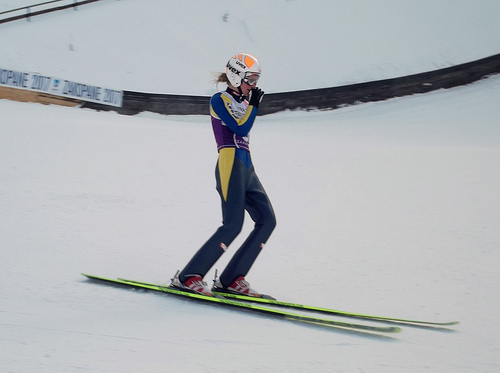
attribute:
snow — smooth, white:
[1, 1, 500, 369]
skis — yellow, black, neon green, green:
[77, 267, 462, 337]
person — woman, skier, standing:
[166, 49, 280, 300]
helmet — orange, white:
[222, 49, 265, 92]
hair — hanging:
[210, 70, 229, 91]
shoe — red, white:
[173, 269, 217, 300]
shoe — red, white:
[215, 271, 262, 299]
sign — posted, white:
[1, 65, 128, 112]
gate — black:
[0, 0, 499, 122]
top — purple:
[207, 108, 256, 154]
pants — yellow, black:
[174, 144, 280, 290]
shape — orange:
[228, 51, 260, 73]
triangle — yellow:
[216, 145, 238, 207]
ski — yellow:
[77, 268, 405, 338]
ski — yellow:
[114, 272, 464, 330]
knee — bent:
[251, 211, 280, 236]